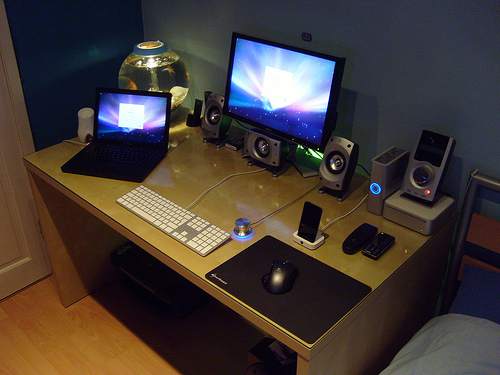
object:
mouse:
[263, 257, 298, 295]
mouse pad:
[203, 234, 372, 345]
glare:
[261, 259, 298, 295]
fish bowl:
[118, 38, 191, 113]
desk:
[22, 104, 458, 373]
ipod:
[298, 201, 324, 243]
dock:
[292, 226, 325, 249]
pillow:
[452, 263, 499, 321]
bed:
[385, 168, 498, 375]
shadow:
[34, 172, 297, 375]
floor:
[0, 272, 264, 375]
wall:
[3, 0, 145, 151]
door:
[0, 6, 55, 306]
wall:
[142, 1, 499, 217]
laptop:
[61, 87, 173, 184]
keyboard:
[116, 184, 233, 258]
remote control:
[340, 222, 378, 254]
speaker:
[201, 93, 230, 146]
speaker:
[314, 135, 357, 201]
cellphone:
[361, 231, 396, 259]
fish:
[164, 65, 177, 77]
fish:
[118, 75, 137, 91]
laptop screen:
[98, 90, 168, 145]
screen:
[227, 38, 336, 143]